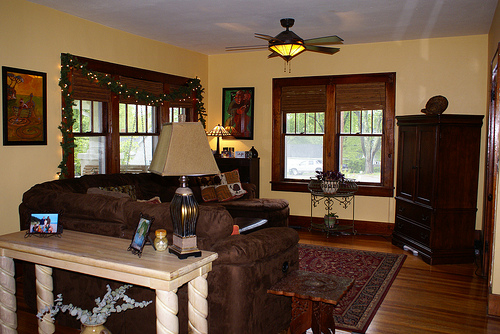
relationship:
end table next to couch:
[266, 269, 355, 332] [19, 172, 300, 333]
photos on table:
[22, 203, 184, 262] [9, 213, 184, 330]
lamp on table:
[149, 108, 219, 258] [0, 224, 226, 324]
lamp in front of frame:
[206, 123, 231, 158] [222, 87, 255, 141]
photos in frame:
[30, 214, 58, 233] [201, 77, 292, 152]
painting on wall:
[219, 86, 258, 138] [208, 32, 488, 233]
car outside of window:
[280, 147, 336, 184] [276, 86, 385, 193]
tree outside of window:
[343, 116, 379, 169] [272, 78, 392, 187]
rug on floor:
[268, 239, 415, 332] [265, 239, 479, 332]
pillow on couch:
[200, 169, 248, 202] [16, 176, 299, 333]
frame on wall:
[222, 87, 255, 141] [208, 32, 488, 233]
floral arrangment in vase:
[38, 280, 152, 332] [82, 321, 113, 331]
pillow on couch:
[209, 170, 251, 205] [19, 164, 289, 309]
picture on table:
[126, 215, 153, 257] [0, 225, 217, 332]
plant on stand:
[306, 159, 353, 214] [310, 179, 355, 241]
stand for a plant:
[310, 179, 355, 241] [306, 159, 353, 214]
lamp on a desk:
[206, 122, 238, 152] [209, 143, 259, 196]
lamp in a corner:
[206, 122, 238, 152] [191, 52, 227, 152]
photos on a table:
[30, 214, 58, 233] [16, 213, 212, 295]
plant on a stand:
[315, 170, 347, 228] [308, 178, 357, 238]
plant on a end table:
[315, 170, 347, 228] [266, 269, 355, 332]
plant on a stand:
[315, 170, 347, 228] [0, 220, 218, 332]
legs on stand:
[139, 284, 238, 332] [0, 229, 217, 333]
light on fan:
[267, 39, 305, 59] [224, 32, 347, 75]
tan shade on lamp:
[157, 128, 242, 186] [155, 123, 221, 256]